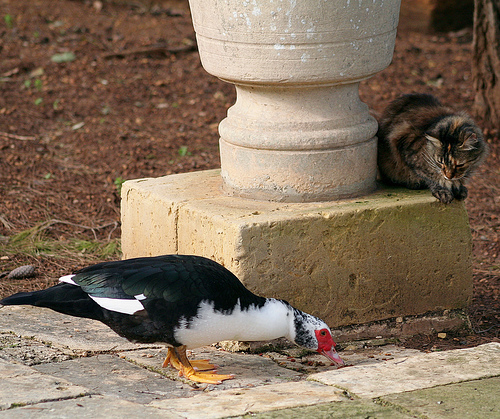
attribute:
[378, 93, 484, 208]
cat — sitting, dark brown, brown, watching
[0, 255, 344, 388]
duck — black, white, standing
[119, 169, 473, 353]
block — concrete, gray, rectangular, light gray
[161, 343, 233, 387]
feet — orange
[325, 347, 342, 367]
beak — red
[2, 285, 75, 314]
tail — black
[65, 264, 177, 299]
wings — black, white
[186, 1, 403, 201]
pot — concrete, gray, cement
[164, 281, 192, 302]
feather — black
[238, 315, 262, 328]
feather — white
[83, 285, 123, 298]
feather — dark green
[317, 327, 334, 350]
marking — red